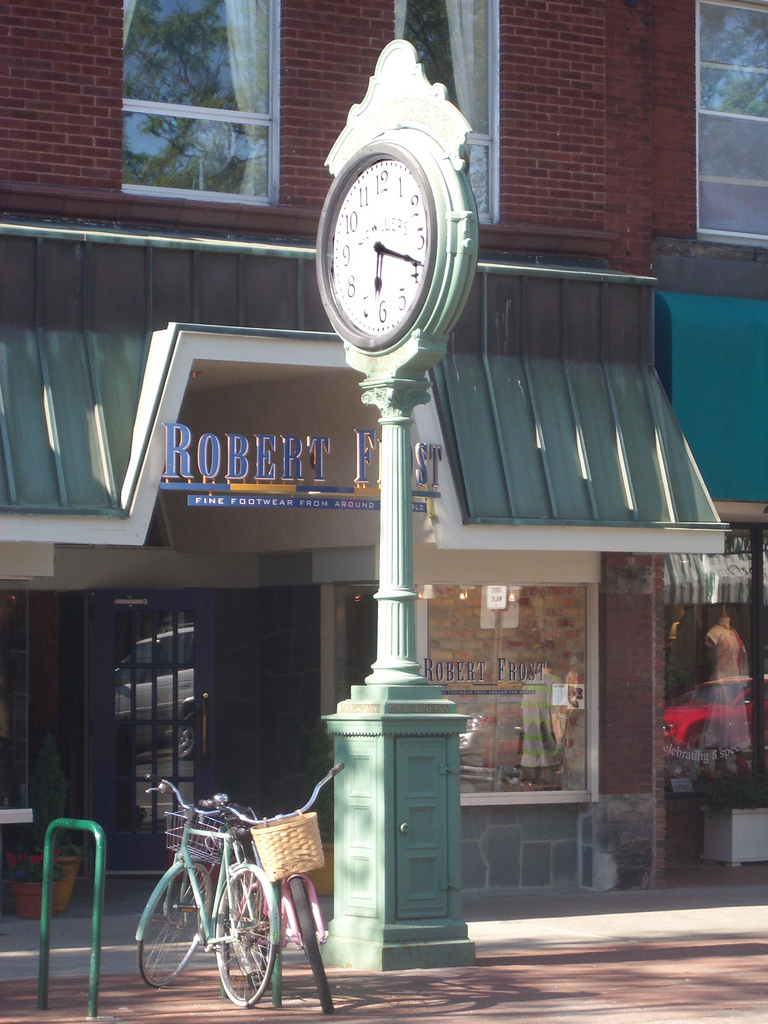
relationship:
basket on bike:
[245, 806, 325, 882] [217, 761, 348, 1012]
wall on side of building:
[10, 4, 653, 792] [3, 1, 766, 926]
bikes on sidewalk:
[129, 766, 285, 1012] [0, 882, 761, 1013]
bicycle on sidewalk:
[199, 758, 334, 1013] [9, 875, 764, 1021]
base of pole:
[332, 670, 467, 977] [316, 372, 477, 972]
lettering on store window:
[413, 642, 559, 702] [425, 580, 592, 785]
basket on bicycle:
[245, 807, 325, 883] [203, 762, 345, 1013]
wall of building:
[5, 2, 694, 268] [3, 1, 766, 926]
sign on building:
[164, 417, 443, 513] [3, 1, 766, 926]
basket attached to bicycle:
[245, 807, 325, 883] [198, 755, 349, 1013]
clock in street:
[313, 142, 440, 348] [6, 890, 764, 1015]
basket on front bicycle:
[245, 807, 325, 883] [198, 755, 349, 1013]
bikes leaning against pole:
[113, 776, 378, 1011] [277, 22, 535, 1000]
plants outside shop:
[4, 644, 104, 934] [14, 203, 702, 951]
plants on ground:
[4, 644, 104, 934] [10, 806, 765, 1015]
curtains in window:
[105, 0, 294, 212] [382, 505, 617, 849]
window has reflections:
[402, 563, 619, 838] [382, 553, 608, 811]